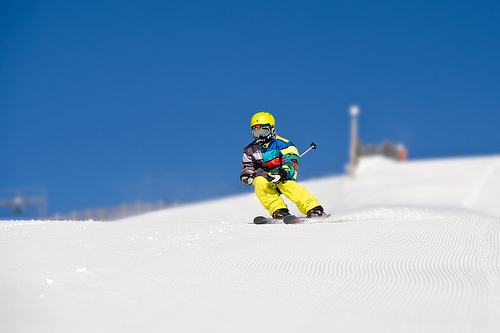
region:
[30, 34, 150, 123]
The sky is blue.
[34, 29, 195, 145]
The sky is clear.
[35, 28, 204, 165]
The sky is bright.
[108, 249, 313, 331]
The snow is bright.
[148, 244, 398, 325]
The snow is white.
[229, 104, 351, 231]
The person is skiing.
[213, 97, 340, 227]
The person is wearing yellow pants.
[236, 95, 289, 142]
The person is wearing a yellow helmet.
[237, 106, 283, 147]
The person is wearing goggles.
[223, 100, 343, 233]
The person is skiing.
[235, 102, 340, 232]
a skier going down the hill fast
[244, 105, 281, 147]
skier's head covered by goggles and helmet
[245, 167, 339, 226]
yellow snow pants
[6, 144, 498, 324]
hill covered in soft snow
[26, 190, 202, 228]
a blurry fence in the background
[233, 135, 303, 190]
a colorful jacket on the skier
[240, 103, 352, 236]
a person on ski's leaning to there right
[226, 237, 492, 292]
curvy ripples in the snow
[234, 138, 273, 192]
half of skier's jacket is black and white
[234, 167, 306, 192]
black and white ski gloves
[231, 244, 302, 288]
The snow is white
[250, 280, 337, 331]
The snow is white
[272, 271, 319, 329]
The snow is white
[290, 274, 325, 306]
The snow is white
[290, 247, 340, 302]
The snow is white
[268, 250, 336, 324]
The snow is white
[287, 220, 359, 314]
The snow is white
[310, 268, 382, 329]
The snow is white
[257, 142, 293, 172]
multi colored stripes on a ski coat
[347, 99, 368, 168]
a white tower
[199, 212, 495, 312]
ripples in white snow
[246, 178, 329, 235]
neon yellow ski pants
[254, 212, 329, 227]
black skis on a skier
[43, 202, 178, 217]
elongated blurry fence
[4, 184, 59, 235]
blurred ski lift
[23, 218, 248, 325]
smooth snow hill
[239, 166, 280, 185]
white gloves on a skier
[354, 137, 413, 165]
gray blurred structure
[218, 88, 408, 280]
a skier going down a hill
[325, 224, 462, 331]
ski lines in white snow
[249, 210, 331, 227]
a pair of black skis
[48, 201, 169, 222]
a metal fence in the background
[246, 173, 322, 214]
yellow pants on a skier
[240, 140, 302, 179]
a multi colored ski coat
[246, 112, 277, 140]
a skier's yellow helmet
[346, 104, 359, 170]
a tall blurred white pole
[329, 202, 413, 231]
a spray of snow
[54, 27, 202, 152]
a vivid blue sky